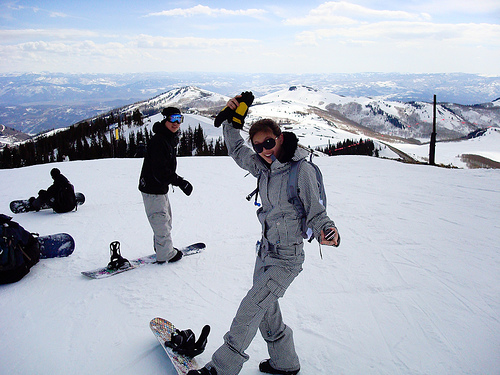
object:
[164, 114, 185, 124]
goggles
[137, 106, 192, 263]
man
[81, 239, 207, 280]
snow board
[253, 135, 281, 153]
glasses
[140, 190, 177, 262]
pants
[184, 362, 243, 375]
foot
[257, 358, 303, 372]
foot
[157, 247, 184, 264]
foot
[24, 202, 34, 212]
foot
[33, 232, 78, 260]
snowboard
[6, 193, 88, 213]
snowboard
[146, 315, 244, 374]
snowboard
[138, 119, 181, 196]
black jacket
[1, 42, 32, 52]
clouds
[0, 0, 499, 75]
sky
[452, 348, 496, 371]
ground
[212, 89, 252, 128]
glove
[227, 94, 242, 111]
hand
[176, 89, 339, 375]
people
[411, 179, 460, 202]
ground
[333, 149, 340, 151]
red line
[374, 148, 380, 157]
trees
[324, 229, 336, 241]
device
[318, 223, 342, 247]
hand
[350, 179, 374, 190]
snow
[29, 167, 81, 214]
man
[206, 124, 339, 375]
ski suit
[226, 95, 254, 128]
gloves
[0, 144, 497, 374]
mountain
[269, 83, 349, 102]
mountains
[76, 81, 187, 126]
hill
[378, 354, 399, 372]
snow